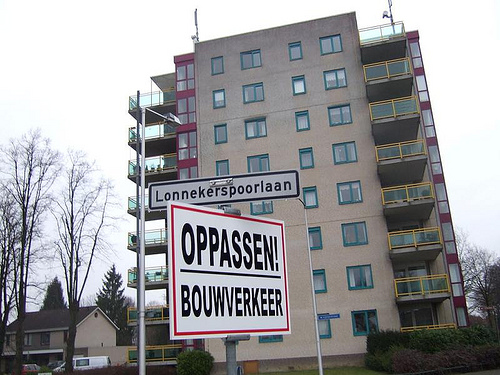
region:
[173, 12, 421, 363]
The building is tall.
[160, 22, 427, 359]
The building has windows in it.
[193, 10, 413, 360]
The building is off white.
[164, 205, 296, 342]
A sign.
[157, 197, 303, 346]
The sign is white.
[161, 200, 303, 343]
The sign has black letters.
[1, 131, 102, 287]
Trees are in the picture.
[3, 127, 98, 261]
The trees have no leaves.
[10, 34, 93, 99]
The sky is white.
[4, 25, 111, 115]
The sky is clear.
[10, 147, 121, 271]
tall trees with no leaves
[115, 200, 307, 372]
black red and white sign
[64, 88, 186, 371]
a tallsilver light pole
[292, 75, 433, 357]
a tall building with balconys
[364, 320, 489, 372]
green and purple bushes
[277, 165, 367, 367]
windows with blue trim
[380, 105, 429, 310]
balcony with yellow trim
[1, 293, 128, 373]
tan and brown house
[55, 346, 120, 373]
a parked white van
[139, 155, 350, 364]
two signs in front of bulding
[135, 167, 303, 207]
black and white street sign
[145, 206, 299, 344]
square red, black and white street sign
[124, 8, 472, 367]
tall tan building with blue framed windows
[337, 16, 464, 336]
yellow framed glass guard rails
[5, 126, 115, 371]
tall leafless trees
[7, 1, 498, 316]
white cloudless sky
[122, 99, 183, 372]
silver metal street light on a pole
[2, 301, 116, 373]
tan house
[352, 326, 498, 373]
short green bushes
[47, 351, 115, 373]
white van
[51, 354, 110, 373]
A white van.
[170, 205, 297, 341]
A sign on the post.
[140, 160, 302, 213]
A white street sign.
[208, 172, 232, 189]
A bracket on the street sign.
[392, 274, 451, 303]
A yellow balcony rail.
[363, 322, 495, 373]
Bushes by the building.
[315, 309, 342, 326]
A blue street sign.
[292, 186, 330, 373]
A street lamp on the sidewalk.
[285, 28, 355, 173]
A row of windows.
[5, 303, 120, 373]
A house on the corner.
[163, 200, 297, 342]
Oppassen! Bouwverkeer sign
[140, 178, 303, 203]
Lonnekerspooriaan sign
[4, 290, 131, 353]
small apartment building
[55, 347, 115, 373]
a white van parked on the road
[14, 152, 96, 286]
trees growing in front of the building.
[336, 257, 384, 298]
second floor window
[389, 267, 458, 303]
second floor balcony.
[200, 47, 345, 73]
top floor windows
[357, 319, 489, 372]
shrubbery planted out front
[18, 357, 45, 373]
car parked on the road